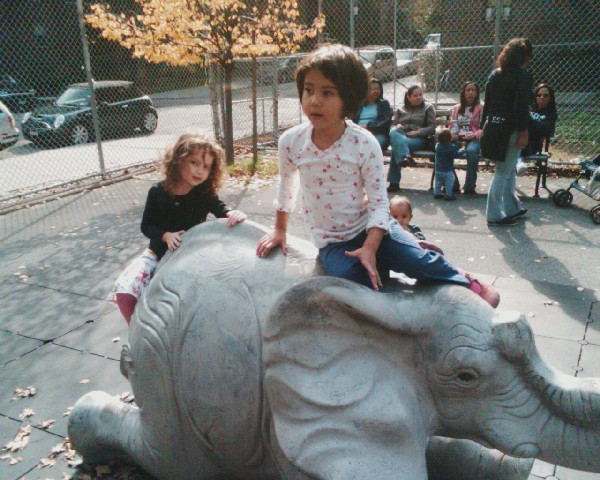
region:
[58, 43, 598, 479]
little girl on top of elephant statue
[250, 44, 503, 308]
little girl wearing white flowered top and blue pants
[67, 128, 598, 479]
little girl behind elephant statue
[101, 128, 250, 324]
little girl wearing black top and flowered skirt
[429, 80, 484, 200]
small child standing in front of woman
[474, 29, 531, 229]
woman is standing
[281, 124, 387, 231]
girl wearing a white shirt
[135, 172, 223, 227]
girl wearing a black shirt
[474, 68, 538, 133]
girl wearing a black shirt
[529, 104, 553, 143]
girl wearing a black shirt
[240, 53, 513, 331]
Girl sitting on a cement elephant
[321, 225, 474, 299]
girl wearing blue jeans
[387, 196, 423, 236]
baby standing behind the girl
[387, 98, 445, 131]
woman wearing a gray jacket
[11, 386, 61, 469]
leaves on the ground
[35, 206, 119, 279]
leaves on the ground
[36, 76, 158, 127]
Small car driving on road.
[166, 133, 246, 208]
Girl has brown hair.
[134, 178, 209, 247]
Girl wearing black shirt.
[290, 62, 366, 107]
Girl has brown hair.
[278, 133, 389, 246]
Girl wearing long sleeve shirt.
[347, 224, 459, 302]
Girl wearing blue pants.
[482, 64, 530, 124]
Person wearing black shirt.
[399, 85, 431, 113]
Person has dark hair.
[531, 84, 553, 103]
Sunglasses on person's face.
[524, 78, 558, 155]
A woman is sitting on a bench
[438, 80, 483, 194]
A woman is sitting on a bench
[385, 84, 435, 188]
A woman is sitting on a bench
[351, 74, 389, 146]
A woman is sitting on a bench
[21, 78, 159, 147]
A car is parked on the street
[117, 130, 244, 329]
A girl is playing on a statue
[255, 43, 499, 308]
A girl is playing on a statue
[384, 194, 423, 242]
A baby is playing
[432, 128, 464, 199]
A baby is playing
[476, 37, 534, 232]
A woman is standing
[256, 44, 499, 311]
A girl sitting on an elephant statue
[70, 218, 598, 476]
An elephant statue in a park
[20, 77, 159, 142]
A car on the street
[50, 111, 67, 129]
A headlight on a car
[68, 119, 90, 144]
A tire on a car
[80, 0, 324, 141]
A tree in the city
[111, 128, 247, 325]
A girl beside an elephant statue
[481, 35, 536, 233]
A woman standing in the park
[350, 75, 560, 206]
People sitting on a bench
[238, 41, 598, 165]
A fence in the park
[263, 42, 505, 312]
a person is sitting down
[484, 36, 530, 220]
a person is standing up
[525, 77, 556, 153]
a person is sitting down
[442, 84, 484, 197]
a person is sitting down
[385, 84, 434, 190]
a person is sitting down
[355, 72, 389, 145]
a person is sitting down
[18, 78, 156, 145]
a car on a street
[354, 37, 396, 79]
a car on a street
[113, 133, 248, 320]
little girl is climbing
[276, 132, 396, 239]
The shirt has red spots on it.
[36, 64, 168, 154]
The car is parked on side of road.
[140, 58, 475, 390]
Kids are sitting on top of the elephant.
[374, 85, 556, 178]
People sitting onthe bench.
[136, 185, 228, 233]
The shirt is black.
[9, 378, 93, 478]
Leaves on the ground.